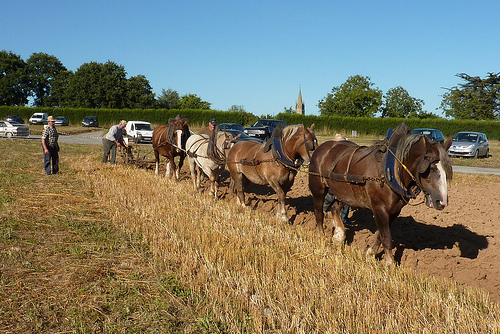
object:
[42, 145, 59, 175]
jeans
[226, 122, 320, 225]
brown horse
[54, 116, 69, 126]
car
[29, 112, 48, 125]
car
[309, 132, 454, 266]
horse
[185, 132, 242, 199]
horse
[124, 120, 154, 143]
car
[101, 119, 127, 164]
man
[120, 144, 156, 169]
plow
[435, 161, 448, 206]
marking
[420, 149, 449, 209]
face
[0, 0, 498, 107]
cloud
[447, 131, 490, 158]
car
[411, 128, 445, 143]
car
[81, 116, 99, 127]
car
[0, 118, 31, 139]
car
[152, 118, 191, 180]
brown horse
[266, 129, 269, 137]
wall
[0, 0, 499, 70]
sky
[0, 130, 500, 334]
field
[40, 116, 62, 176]
man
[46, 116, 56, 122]
cap